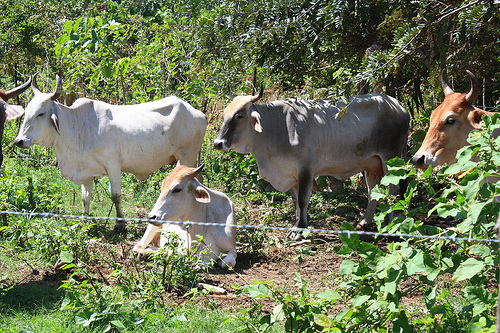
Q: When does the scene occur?
A: Daytime.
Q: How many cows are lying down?
A: One.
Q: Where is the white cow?
A: On the left.